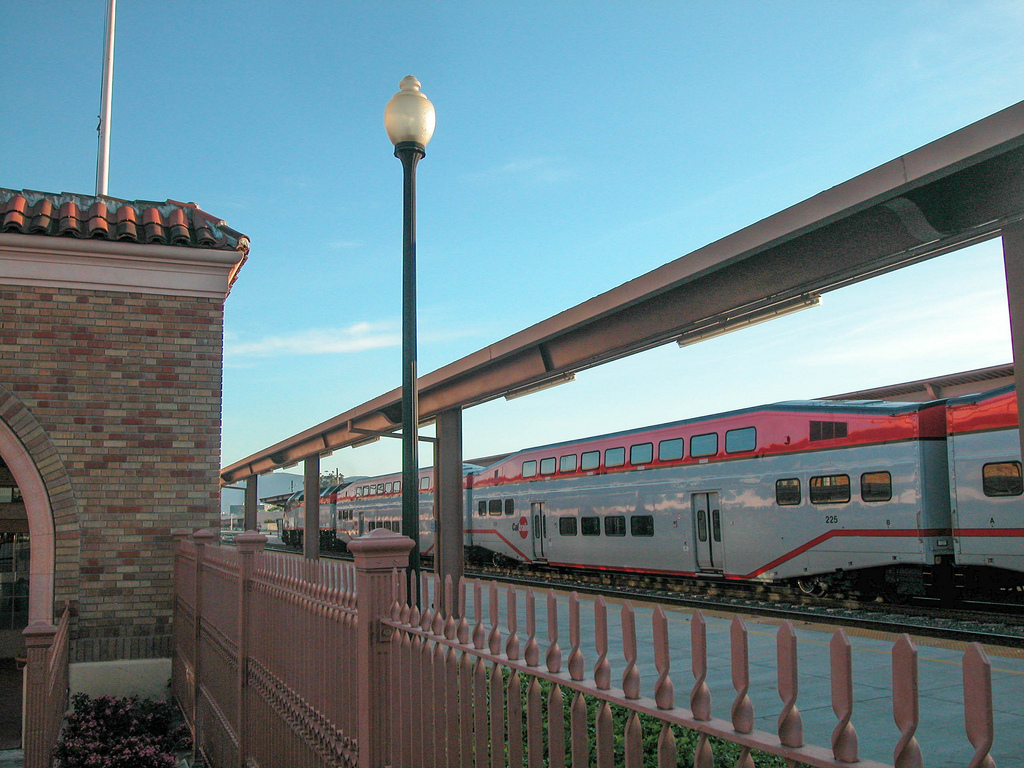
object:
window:
[857, 460, 893, 502]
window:
[853, 475, 899, 507]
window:
[978, 462, 1017, 499]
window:
[621, 510, 652, 537]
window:
[580, 510, 597, 536]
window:
[499, 495, 516, 515]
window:
[484, 497, 503, 511]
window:
[484, 495, 508, 516]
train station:
[2, 88, 1023, 765]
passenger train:
[275, 350, 1013, 593]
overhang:
[225, 101, 1019, 479]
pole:
[389, 143, 427, 608]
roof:
[5, 163, 274, 345]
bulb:
[384, 77, 437, 146]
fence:
[178, 518, 1024, 763]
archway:
[0, 197, 247, 764]